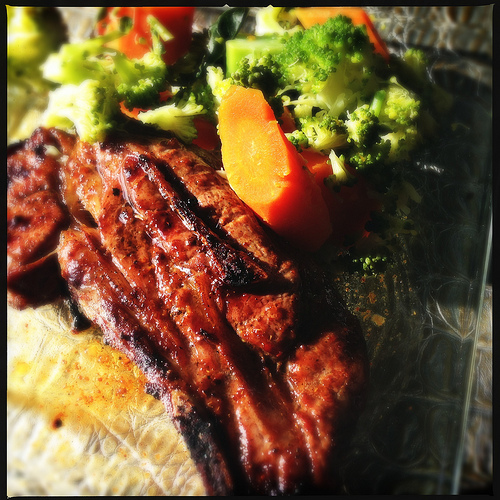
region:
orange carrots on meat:
[203, 78, 336, 240]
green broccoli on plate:
[286, 38, 421, 158]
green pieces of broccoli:
[35, 13, 206, 106]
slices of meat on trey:
[2, 137, 348, 498]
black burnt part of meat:
[178, 193, 243, 297]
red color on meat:
[73, 235, 143, 309]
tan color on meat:
[75, 170, 107, 216]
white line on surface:
[430, 258, 490, 498]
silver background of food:
[378, 265, 498, 488]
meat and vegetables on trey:
[0, 11, 440, 444]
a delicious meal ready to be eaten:
[16, 17, 438, 499]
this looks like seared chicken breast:
[6, 117, 372, 497]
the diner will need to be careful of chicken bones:
[129, 151, 285, 303]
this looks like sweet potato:
[206, 75, 335, 253]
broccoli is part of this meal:
[249, 14, 425, 173]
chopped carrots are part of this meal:
[281, 8, 407, 60]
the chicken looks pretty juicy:
[8, 112, 378, 494]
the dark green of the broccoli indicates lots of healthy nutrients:
[269, 18, 434, 170]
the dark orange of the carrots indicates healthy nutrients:
[93, 7, 394, 66]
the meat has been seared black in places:
[97, 290, 238, 498]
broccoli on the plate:
[261, 21, 400, 148]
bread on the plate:
[31, 368, 126, 424]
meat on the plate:
[142, 274, 287, 370]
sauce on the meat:
[206, 307, 307, 411]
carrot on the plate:
[210, 58, 337, 240]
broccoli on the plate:
[27, 40, 156, 95]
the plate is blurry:
[424, 18, 480, 47]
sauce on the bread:
[65, 365, 152, 425]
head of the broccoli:
[275, 36, 347, 96]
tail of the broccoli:
[41, 87, 120, 128]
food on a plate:
[0, 24, 474, 477]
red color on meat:
[107, 197, 132, 241]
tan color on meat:
[85, 187, 108, 231]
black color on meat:
[139, 329, 172, 389]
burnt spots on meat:
[173, 204, 250, 284]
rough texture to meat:
[100, 185, 192, 301]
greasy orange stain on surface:
[48, 346, 120, 418]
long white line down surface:
[438, 293, 490, 498]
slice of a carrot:
[197, 82, 343, 256]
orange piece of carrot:
[200, 80, 339, 229]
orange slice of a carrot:
[222, 96, 343, 233]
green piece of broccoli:
[310, 45, 412, 150]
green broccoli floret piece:
[291, 35, 418, 135]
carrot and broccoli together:
[211, 24, 395, 214]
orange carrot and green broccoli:
[203, 37, 394, 221]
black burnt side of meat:
[152, 163, 214, 248]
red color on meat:
[128, 171, 153, 275]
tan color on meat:
[77, 165, 102, 198]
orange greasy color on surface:
[32, 358, 119, 460]